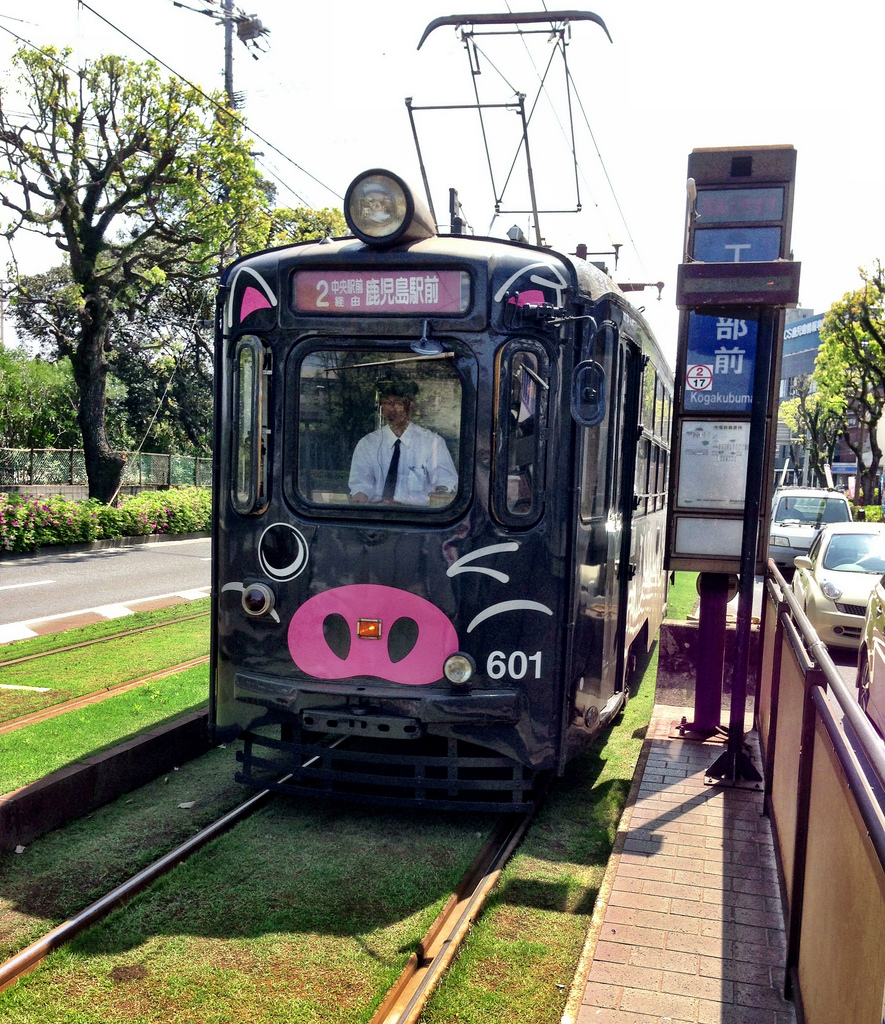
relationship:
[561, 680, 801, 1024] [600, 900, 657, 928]
platform has brick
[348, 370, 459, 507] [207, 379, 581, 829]
driving that driving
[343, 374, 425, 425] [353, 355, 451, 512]
head of a man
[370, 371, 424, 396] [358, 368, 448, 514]
hat of man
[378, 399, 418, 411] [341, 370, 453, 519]
face of man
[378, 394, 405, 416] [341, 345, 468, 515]
glassses of man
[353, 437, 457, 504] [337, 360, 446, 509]
shirt of a man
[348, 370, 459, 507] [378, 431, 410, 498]
driving wears tie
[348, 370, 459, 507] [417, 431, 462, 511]
driving has arm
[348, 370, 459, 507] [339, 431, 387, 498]
driving has arm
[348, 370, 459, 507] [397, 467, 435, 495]
driving has pocket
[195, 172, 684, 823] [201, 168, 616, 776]
train has front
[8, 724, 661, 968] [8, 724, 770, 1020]
shadow on ground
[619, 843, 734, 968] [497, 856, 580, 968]
bricks next grass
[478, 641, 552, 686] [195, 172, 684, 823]
number on train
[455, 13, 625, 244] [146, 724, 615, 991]
wires above ground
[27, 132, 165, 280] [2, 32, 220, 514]
branches on tree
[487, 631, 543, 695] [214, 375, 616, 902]
number on train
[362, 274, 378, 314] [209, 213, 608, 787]
number on train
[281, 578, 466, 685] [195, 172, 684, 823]
logo on train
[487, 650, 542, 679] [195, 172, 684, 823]
numbers on train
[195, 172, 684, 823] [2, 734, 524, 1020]
train on tracks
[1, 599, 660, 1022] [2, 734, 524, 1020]
grass under tracks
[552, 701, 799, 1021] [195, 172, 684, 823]
platform next to train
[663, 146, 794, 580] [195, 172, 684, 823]
sign near train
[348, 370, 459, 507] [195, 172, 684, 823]
driving on train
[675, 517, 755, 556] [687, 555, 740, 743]
sign on pole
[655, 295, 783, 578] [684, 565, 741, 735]
sign on pole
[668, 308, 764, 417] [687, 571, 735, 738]
sign on pole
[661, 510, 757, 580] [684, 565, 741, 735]
sign on pole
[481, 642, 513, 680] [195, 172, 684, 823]
number on train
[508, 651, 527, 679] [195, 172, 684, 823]
number on train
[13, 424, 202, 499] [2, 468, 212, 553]
fence on side of flowers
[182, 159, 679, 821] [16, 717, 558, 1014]
train car on train tracks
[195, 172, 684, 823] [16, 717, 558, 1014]
train on tracks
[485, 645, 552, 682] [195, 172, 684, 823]
numbers on black train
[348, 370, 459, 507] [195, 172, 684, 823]
driving driving train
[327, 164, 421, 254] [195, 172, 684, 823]
light on top of train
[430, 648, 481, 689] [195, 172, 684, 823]
light on train